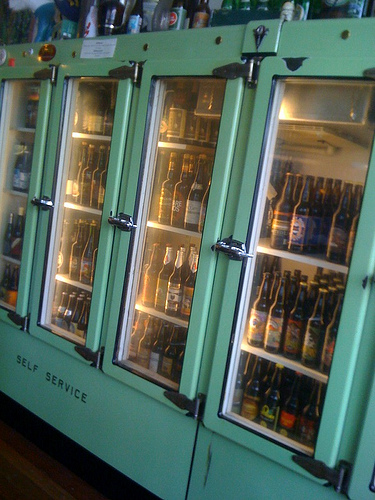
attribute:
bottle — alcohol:
[289, 173, 315, 252]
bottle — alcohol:
[325, 184, 350, 261]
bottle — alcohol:
[246, 273, 273, 348]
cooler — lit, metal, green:
[0, 17, 373, 498]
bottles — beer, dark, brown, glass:
[270, 172, 359, 264]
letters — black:
[17, 355, 89, 405]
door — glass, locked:
[101, 72, 246, 421]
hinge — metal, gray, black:
[246, 58, 255, 85]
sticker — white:
[81, 40, 120, 59]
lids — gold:
[285, 171, 362, 191]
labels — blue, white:
[272, 210, 354, 254]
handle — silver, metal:
[109, 213, 141, 229]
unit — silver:
[192, 82, 373, 154]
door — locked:
[202, 54, 373, 483]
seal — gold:
[38, 44, 59, 62]